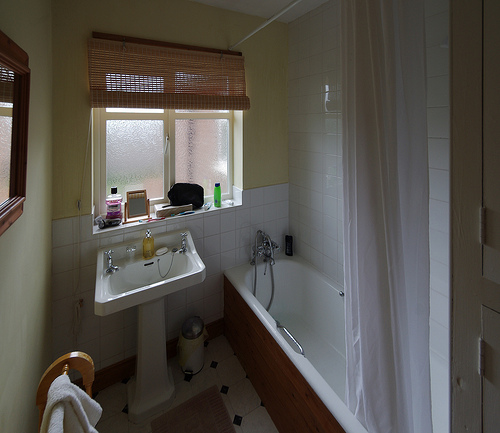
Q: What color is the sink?
A: White.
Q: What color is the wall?
A: Yellow.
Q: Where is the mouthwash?
A: In the windowsill.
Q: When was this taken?
A: Daytime.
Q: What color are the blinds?
A: Brown.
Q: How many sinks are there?
A: 1.